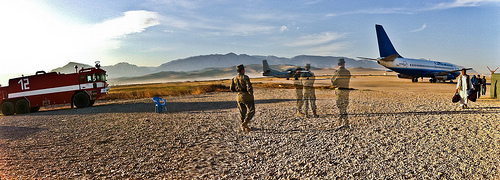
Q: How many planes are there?
A: 2.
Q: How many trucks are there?
A: 1.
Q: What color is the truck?
A: Red and whtie.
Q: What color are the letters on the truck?
A: White.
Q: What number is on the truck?
A: 12.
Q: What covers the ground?
A: Sand.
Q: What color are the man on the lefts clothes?
A: Brown.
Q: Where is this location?
A: A desert.